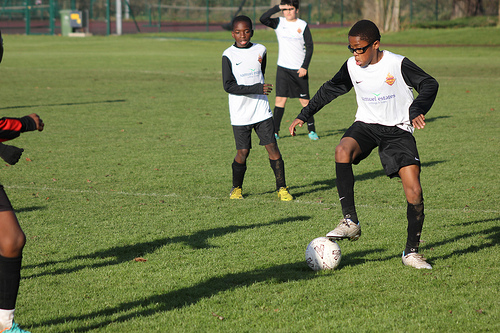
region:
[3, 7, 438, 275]
Four boys playing soccer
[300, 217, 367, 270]
boy's soccer cleats on soccer ball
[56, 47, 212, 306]
soccer field with shadows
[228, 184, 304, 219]
yellow boy's soccer cleats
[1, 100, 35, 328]
boys with red and black uniform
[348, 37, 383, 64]
boy with sports goggles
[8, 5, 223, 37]
tennis courts with garbage cans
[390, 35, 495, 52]
dark red walkway to tennis courts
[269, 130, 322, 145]
light blue soccer cleats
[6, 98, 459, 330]
boys wearing black shinguards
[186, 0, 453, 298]
three boys on a soccer field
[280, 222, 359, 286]
a white and black soccer ball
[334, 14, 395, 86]
a boy wearing glasses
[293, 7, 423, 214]
a boy wearing a black and white shirt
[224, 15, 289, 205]
a boy wearing yellow shoes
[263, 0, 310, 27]
a boy raising his hand to his face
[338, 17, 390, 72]
a boy with short black hair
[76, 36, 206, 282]
a soccer field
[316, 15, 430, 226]
a boy wearing black shorts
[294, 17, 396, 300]
a boy with his foot on a soccer ball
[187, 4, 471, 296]
three kids playing soccer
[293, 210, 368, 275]
foot on the ball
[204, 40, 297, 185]
white and black uniform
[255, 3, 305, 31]
head lifted up to eyes to block out sun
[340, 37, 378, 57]
thin rimmed black glasses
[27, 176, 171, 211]
faded white line on the grass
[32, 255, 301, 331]
shadow on the grass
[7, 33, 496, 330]
large soccer field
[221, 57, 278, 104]
hand in front of body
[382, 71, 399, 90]
small logo on the jersey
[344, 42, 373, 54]
Black glasses on a boy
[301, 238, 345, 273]
White soccer ball in the grass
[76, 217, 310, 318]
Shadows of children in the grass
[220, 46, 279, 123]
Boy wearing a white shirt playing soccer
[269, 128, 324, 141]
Boy wearing blue shoes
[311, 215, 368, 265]
Boy's right foot on a soccer ball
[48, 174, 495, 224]
White line on a soccer field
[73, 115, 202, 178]
Green grass on a soccer field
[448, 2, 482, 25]
Tree trunk behind a soccer field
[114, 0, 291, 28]
Tennis court behind a soccer field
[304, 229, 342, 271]
A white soccer ball.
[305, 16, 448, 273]
A boy kicking soccer ball.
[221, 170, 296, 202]
Yellow soccer cleats.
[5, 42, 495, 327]
A grassy soccer field.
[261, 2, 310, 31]
A boy touching his face.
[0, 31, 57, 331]
A goalie wearing a red and black shirt.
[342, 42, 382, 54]
Black glasses on a boy's face.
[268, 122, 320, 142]
Blue soccer cleats.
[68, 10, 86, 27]
A electrical box on side of field.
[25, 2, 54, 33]
A green chain link fence door.